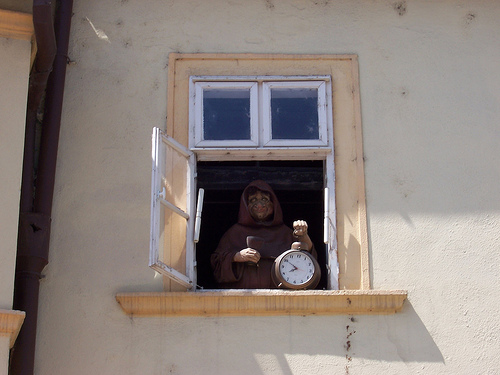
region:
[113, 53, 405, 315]
window with unfinished wooden frame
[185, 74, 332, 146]
double panes with whitewashed frames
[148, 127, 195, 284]
open whitewashed window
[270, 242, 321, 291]
over-sized alarm clock with white face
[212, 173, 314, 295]
old looking maniquin wearing monks robes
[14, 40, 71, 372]
dark painted beam with heart cut out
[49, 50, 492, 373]
stuccoed outer wall of building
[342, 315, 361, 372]
dark stain on building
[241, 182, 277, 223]
slightly scary face of maniquin in window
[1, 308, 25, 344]
detail on vertical column on out-side of building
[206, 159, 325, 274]
the window is open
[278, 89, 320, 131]
this is a glass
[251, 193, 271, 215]
this is a mask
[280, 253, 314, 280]
this is a clock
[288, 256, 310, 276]
the clock is white in color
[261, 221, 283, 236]
the hood is long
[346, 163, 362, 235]
the frame is wooden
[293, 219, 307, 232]
the hand is brown in color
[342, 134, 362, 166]
the frame is brown in color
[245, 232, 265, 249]
this is a cup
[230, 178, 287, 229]
person wearing a mask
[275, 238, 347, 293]
large clock on a window sill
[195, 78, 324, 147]
two small windows above person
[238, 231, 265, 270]
wooden cup in persons hand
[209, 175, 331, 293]
person wearing a cloak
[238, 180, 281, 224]
cowl over persons head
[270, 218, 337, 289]
large clock in mans left hand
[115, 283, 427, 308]
windowsill below window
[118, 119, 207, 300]
open window to right of person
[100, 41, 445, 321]
window opened in front of person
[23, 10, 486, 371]
this is a building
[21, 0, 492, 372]
the building is big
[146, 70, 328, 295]
this is a window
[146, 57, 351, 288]
the window is open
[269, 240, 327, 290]
this is a clock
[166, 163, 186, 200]
the window is made of glass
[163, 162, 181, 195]
the window is transparent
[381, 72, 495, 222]
this is the wall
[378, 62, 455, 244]
the wall is white in color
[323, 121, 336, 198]
the window frame is wooden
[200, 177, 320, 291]
a person wearing a robe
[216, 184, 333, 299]
the robe is brown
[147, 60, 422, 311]
the person is in the window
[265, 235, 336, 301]
the time is 7:50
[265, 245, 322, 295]
the clock is brown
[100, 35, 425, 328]
the window is brown and white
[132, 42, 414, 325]
the window is made of wood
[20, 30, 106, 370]
a brown drain pipe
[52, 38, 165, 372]
the wall of the building